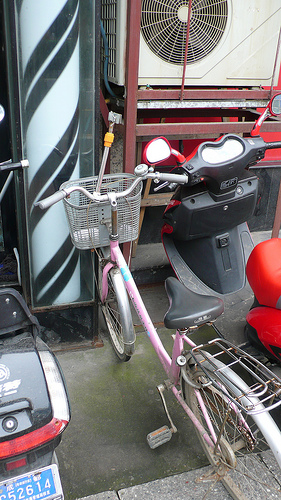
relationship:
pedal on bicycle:
[141, 423, 180, 452] [33, 159, 279, 497]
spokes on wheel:
[109, 301, 117, 327] [95, 260, 132, 366]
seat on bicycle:
[147, 267, 230, 331] [33, 159, 279, 497]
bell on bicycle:
[127, 159, 157, 178] [33, 159, 279, 497]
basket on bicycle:
[57, 172, 142, 250] [33, 159, 279, 497]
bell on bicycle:
[133, 163, 153, 178] [33, 159, 279, 497]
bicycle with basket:
[33, 159, 279, 497] [57, 172, 142, 250]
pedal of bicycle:
[141, 423, 180, 452] [33, 159, 279, 497]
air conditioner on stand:
[120, 3, 277, 94] [96, 3, 279, 275]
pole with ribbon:
[13, 1, 94, 310] [26, 39, 73, 83]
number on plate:
[6, 481, 57, 499] [0, 459, 77, 496]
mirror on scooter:
[137, 133, 175, 167] [130, 90, 280, 375]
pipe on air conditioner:
[93, 107, 122, 199] [120, 3, 277, 94]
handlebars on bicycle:
[34, 169, 193, 213] [33, 159, 279, 497]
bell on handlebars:
[127, 159, 157, 178] [34, 169, 193, 213]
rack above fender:
[181, 334, 279, 413] [195, 346, 279, 411]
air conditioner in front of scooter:
[120, 3, 277, 94] [130, 90, 280, 375]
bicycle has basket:
[33, 159, 279, 497] [57, 172, 142, 250]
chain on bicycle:
[230, 416, 255, 447] [33, 159, 279, 497]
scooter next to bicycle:
[130, 90, 280, 375] [33, 159, 279, 497]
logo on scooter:
[222, 172, 238, 192] [130, 90, 280, 375]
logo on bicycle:
[120, 265, 133, 290] [33, 159, 279, 497]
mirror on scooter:
[266, 90, 280, 123] [130, 90, 280, 375]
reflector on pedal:
[149, 424, 168, 439] [141, 423, 180, 452]